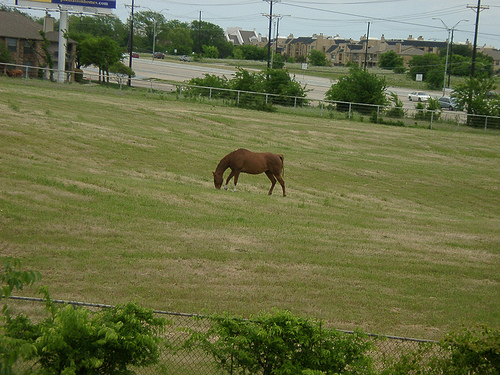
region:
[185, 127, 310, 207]
a horse grazing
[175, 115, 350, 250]
an animal that is brown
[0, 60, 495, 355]
a green field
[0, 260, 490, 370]
a gray fence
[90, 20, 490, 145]
a street with cars here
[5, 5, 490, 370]
a scene outside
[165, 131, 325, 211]
a brown animal here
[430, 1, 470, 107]
a street pole here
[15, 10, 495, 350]
a scene during the day here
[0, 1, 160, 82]
a white sign here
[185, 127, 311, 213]
The horse is standing in a grassy area.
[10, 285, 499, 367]
A fence keeps the horse in one area.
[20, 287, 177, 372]
A bush in front of the fence.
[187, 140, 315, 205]
The horse is brown.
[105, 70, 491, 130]
The other side of the horse fence.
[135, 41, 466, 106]
A street in the distance.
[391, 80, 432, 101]
A car on the street.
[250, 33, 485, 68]
Some buildings in the distance.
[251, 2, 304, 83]
A power pole in the distance.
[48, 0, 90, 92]
A pole attached to a billboard.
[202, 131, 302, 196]
a horse eating grass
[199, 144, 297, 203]
a brown horse eating grass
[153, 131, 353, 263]
a horse eating in a green field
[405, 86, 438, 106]
a white car in a parking lot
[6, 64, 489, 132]
a chain link fence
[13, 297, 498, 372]
many trees laying against a chain link fence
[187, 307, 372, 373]
a green bush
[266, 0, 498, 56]
many telephone phones with hanging wires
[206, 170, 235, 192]
the head of a horse who is grazing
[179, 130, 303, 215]
A horse is eating grass.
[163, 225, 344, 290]
The grass is green and brown.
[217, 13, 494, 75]
Buildings are in the distance.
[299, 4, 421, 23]
The sky is overcast.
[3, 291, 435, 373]
A chain link fence.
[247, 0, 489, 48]
Power lines are in the background.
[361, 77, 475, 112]
Cars are on the road.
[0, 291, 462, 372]
The fence is made of wire.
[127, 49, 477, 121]
A road with cars on it.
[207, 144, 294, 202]
This is a brown horse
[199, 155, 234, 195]
The horse is grazing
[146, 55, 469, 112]
A highway is in the background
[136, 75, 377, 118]
A fence surrounds the pasture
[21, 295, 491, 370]
Bushes are growing along the fence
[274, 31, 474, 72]
A building complex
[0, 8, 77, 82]
A house is here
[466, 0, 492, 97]
This is a telephone pole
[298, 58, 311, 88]
This is a highway sign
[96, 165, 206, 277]
The grass is short